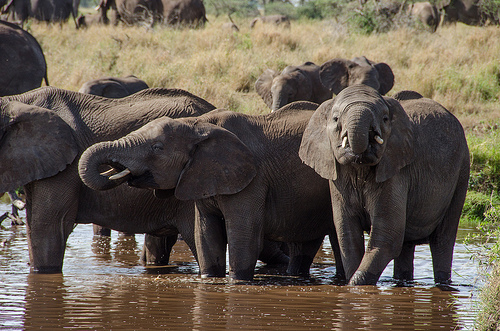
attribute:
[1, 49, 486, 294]
elephants — Large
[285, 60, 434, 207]
head — Grey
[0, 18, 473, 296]
elephants — Grey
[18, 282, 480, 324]
river — shallow, muddy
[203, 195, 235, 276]
leg — Gray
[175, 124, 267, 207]
ear — large, floppy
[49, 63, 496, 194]
riverbank — grassy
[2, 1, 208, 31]
elephants — Grey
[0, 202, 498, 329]
water — very dirty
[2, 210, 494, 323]
water — brown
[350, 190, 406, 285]
leg — Gray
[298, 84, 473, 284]
elephant — Large, Grey, Gray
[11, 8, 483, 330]
park — Large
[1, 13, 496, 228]
grass — green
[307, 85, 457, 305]
elephant — Gray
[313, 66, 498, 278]
elephant — Grey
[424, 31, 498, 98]
grass — green